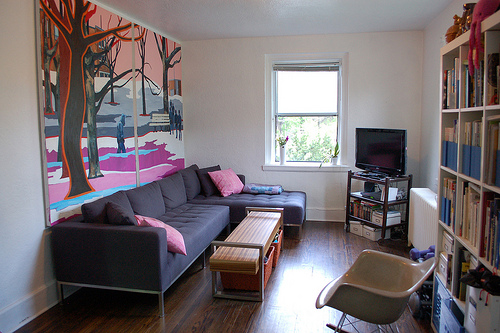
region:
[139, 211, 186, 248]
a pink pillow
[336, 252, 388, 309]
a white chair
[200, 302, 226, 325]
a brown floor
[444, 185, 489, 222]
books on the shelf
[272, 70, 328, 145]
it is a window on the wall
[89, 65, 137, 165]
a painting on the wall behind the black sofa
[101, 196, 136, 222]
black pillows on the black sofa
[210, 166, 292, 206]
a pink and blue pillow on the sofa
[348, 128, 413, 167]
a black tv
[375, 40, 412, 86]
it appears that the wall is white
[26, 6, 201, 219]
A picture with trees is hanging on the wall.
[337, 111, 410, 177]
A black flat screen TV is in the corner.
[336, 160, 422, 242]
The TV is sitting on a shelfing unit.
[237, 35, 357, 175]
A window with a vase on it.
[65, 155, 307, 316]
A black sofa.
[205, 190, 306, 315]
A coffee table with boxes underneath.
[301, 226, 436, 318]
A gray chair.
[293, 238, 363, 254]
The floor is made of wood.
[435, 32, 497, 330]
A large bookcase.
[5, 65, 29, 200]
Part of the wall is white.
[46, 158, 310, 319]
A BLACK SECTIONAL SOFA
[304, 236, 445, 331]
A PLASTIC WHITE CHAIR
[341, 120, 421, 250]
A FLAT SCREEN TV ON A STAND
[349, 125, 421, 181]
A FLAT SCREEN TV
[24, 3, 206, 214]
A PICTURE ON THE WALL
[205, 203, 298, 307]
A WOODEN COFFEE TABLE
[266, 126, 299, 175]
A VASE WITH A FLOWER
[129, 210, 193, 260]
A PINK PILLOW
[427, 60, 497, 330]
A BOOKCASE FILLED WITH BOOKS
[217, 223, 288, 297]
TWO ORANGE CONTAINERS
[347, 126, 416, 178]
A flat screen television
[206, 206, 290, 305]
A coffetable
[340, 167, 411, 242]
A TV stand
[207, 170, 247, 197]
A pink colored small pillow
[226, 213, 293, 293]
Orange baskets under the coffee table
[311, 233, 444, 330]
A white chair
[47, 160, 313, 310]
A wrap around sofa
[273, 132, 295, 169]
A white vase with flowers in it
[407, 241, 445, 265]
Small purple weights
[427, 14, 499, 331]
A bookcase which is full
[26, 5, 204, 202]
painting of trees on the wall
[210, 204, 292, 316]
wood and metal coffee table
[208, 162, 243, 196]
pink throw pillows on the couch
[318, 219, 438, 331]
shiny plastic chair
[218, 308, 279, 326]
dark colored hard wood floors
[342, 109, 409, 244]
television set on a stand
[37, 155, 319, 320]
dark gray sectional couch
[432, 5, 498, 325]
bookshelf next to the chair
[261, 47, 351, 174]
window in the room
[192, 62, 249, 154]
white living room wall